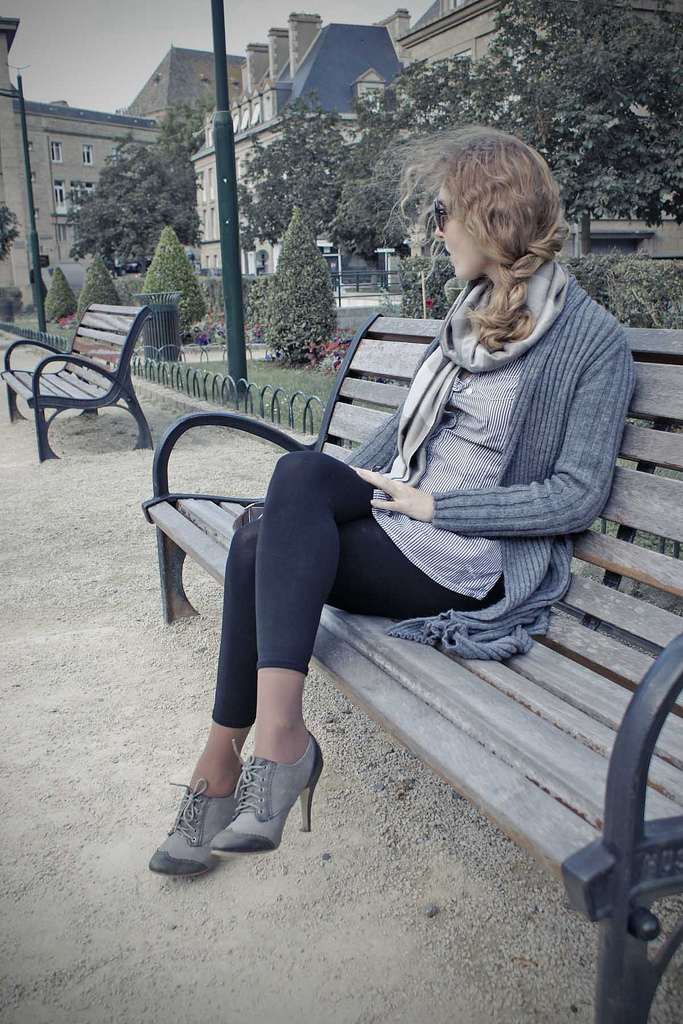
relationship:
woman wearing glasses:
[150, 125, 632, 876] [437, 198, 447, 227]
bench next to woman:
[0, 303, 155, 460] [150, 125, 632, 876]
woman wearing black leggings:
[150, 125, 632, 876] [211, 451, 497, 731]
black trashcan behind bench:
[136, 289, 186, 360] [0, 303, 155, 460]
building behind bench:
[0, 43, 244, 308] [0, 303, 155, 460]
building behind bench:
[196, 10, 407, 268] [0, 303, 155, 460]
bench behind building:
[139, 310, 680, 1021] [371, 0, 682, 266]